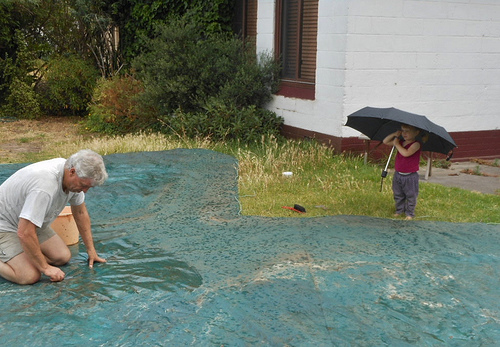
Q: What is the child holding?
A: Umbrella.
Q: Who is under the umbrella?
A: A little boy.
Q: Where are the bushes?
A: Beside the house.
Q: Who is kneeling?
A: The man with white hair.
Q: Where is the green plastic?
A: On the ground.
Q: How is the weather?
A: Rainy.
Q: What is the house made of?
A: Cement blocks.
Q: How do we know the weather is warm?
A: The boy is in a tank top and the man is in shorts and short sleeves.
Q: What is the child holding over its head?
A: Umbrella.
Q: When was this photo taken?
A: Daytime.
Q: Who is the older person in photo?
A: Man.